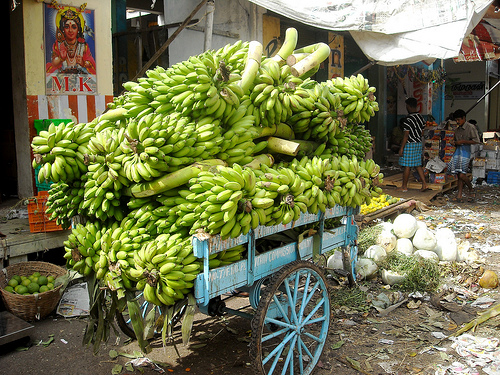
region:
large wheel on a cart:
[245, 236, 334, 372]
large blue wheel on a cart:
[240, 246, 330, 373]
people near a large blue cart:
[388, 87, 480, 189]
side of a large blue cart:
[193, 207, 367, 302]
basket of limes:
[0, 252, 98, 309]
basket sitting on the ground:
[1, 260, 59, 320]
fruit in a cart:
[124, 248, 207, 309]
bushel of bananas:
[34, 128, 92, 196]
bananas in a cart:
[193, 151, 401, 245]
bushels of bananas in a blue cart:
[196, 120, 367, 285]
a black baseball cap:
[400, 94, 420, 105]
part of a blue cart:
[185, 201, 360, 373]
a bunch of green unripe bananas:
[32, 120, 92, 185]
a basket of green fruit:
[0, 261, 65, 320]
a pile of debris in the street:
[455, 327, 498, 373]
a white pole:
[200, 0, 218, 52]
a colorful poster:
[45, 2, 97, 96]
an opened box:
[478, 127, 498, 147]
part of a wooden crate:
[382, 172, 464, 191]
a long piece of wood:
[111, 0, 207, 82]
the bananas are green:
[16, 0, 362, 322]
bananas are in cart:
[13, 17, 413, 372]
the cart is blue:
[183, 220, 385, 363]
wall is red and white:
[24, 95, 114, 150]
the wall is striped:
[28, 82, 120, 149]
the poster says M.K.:
[46, 64, 113, 103]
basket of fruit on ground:
[1, 247, 61, 317]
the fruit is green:
[3, 261, 65, 318]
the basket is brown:
[3, 265, 85, 325]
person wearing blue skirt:
[388, 137, 433, 173]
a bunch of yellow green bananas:
[132, 232, 192, 306]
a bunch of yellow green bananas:
[95, 226, 137, 292]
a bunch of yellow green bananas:
[63, 224, 103, 277]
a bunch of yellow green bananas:
[191, 168, 264, 231]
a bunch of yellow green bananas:
[258, 165, 308, 228]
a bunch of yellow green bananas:
[294, 158, 335, 211]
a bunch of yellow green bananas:
[337, 155, 370, 210]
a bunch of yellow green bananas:
[121, 116, 192, 178]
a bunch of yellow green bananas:
[30, 121, 85, 182]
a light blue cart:
[173, 197, 359, 372]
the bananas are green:
[172, 193, 312, 350]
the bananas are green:
[105, 99, 295, 372]